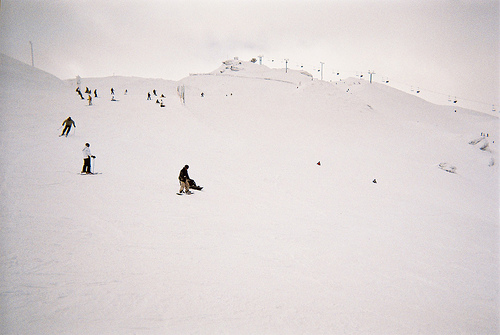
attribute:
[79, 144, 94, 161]
coat — white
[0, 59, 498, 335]
slope — snowy, winter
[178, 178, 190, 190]
pants — brown, tan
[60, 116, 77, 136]
person — daytime, outdoors, skiing, standing, standin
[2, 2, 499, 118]
sky — cloudy, gray, full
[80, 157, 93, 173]
bottoms — black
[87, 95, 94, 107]
man — skiing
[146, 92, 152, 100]
skier — skiing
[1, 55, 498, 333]
mountain — bright, white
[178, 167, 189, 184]
jacket — white